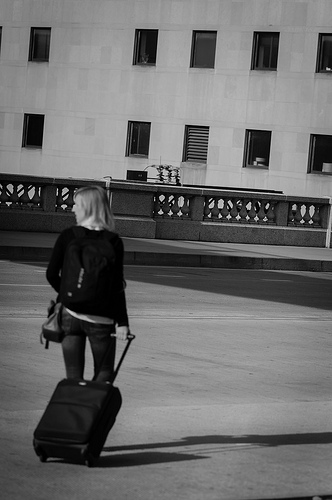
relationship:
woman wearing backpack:
[44, 186, 131, 387] [61, 237, 117, 308]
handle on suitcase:
[88, 330, 133, 383] [28, 327, 136, 461]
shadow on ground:
[89, 432, 320, 466] [258, 76, 280, 104]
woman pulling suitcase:
[44, 186, 131, 387] [31, 332, 135, 466]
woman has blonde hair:
[44, 186, 131, 387] [76, 186, 115, 230]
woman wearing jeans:
[44, 186, 131, 387] [41, 296, 120, 383]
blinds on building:
[250, 31, 281, 72] [1, 0, 330, 220]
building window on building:
[185, 28, 217, 70] [1, 0, 330, 220]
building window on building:
[26, 23, 51, 64] [1, 0, 330, 220]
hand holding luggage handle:
[114, 325, 131, 342] [110, 332, 135, 339]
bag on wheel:
[32, 329, 135, 466] [38, 454, 48, 461]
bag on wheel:
[32, 329, 135, 466] [83, 458, 93, 466]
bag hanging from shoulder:
[39, 291, 65, 350] [52, 224, 83, 255]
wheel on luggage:
[82, 460, 91, 467] [25, 337, 143, 436]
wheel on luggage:
[37, 451, 49, 461] [25, 337, 143, 436]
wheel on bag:
[82, 460, 92, 467] [32, 329, 135, 466]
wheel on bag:
[38, 451, 46, 462] [32, 329, 135, 466]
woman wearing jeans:
[44, 186, 131, 387] [58, 302, 116, 385]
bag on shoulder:
[39, 291, 66, 342] [58, 225, 75, 267]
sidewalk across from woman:
[4, 233, 327, 269] [46, 170, 131, 428]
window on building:
[242, 128, 275, 170] [1, 0, 330, 220]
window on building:
[254, 32, 277, 70] [1, 0, 330, 220]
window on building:
[128, 122, 151, 157] [1, 0, 330, 220]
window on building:
[21, 112, 42, 148] [1, 0, 330, 220]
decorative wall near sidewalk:
[3, 166, 331, 242] [1, 225, 331, 273]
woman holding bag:
[28, 182, 134, 380] [32, 329, 140, 460]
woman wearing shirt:
[28, 182, 134, 380] [58, 306, 116, 324]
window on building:
[242, 128, 275, 170] [0, 0, 331, 199]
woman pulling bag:
[44, 186, 131, 387] [32, 329, 135, 466]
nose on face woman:
[70, 201, 77, 213] [44, 182, 141, 390]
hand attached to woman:
[114, 325, 132, 342] [41, 183, 116, 386]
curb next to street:
[2, 246, 331, 273] [2, 261, 330, 446]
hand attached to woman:
[114, 325, 131, 342] [29, 178, 146, 398]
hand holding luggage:
[114, 325, 131, 342] [17, 314, 160, 470]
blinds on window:
[248, 23, 293, 86] [245, 29, 285, 76]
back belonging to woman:
[59, 225, 119, 316] [29, 187, 140, 465]